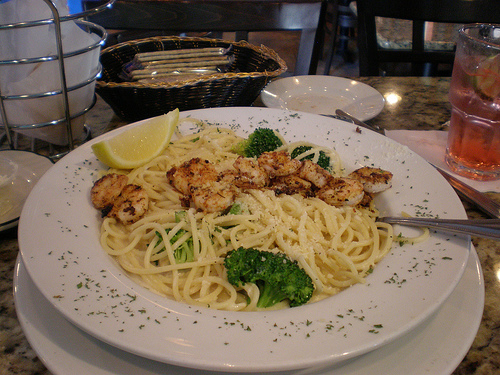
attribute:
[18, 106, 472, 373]
bowl — white, shallow, large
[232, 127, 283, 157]
broccoli — small, green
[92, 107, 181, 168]
lemon — sliced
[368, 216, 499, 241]
utensil — silver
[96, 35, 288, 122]
basket — wicker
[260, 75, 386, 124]
plate — small, white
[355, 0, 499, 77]
seat — black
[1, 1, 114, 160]
basket — metal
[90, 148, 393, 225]
shrimp — grilled